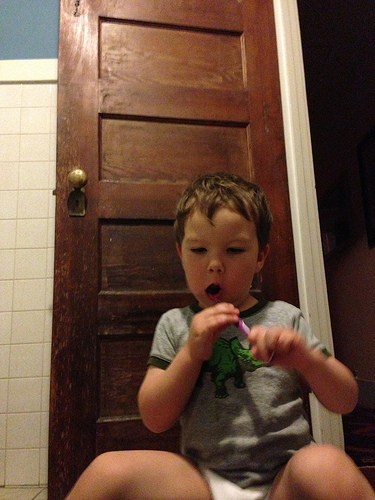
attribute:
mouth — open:
[202, 281, 223, 302]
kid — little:
[62, 171, 373, 498]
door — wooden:
[46, 0, 311, 498]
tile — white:
[0, 81, 56, 485]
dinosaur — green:
[197, 332, 274, 397]